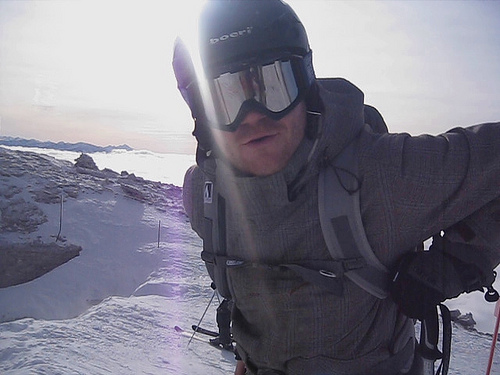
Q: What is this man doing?
A: Skiing or snowboarding.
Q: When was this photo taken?
A: During the day during winter.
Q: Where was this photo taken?
A: On a snow slope.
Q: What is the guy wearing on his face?
A: Goggles.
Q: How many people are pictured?
A: Just 1 man.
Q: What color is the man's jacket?
A: Grey.